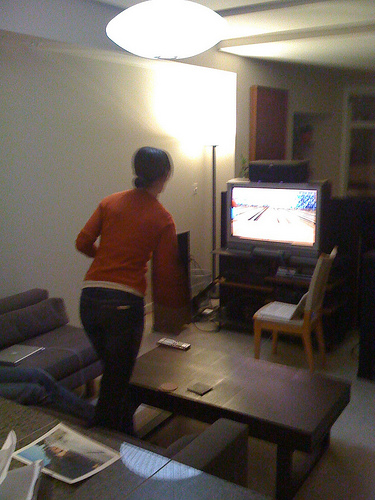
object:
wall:
[4, 36, 240, 282]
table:
[125, 340, 350, 500]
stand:
[319, 430, 330, 453]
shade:
[194, 111, 235, 155]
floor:
[148, 312, 371, 494]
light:
[105, 0, 228, 61]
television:
[226, 178, 321, 268]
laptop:
[260, 291, 309, 321]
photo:
[10, 421, 122, 487]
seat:
[253, 247, 339, 373]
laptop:
[0, 344, 45, 367]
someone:
[294, 124, 314, 161]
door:
[292, 111, 329, 181]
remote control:
[158, 337, 191, 351]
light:
[142, 59, 237, 161]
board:
[0, 59, 238, 276]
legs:
[276, 443, 293, 498]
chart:
[248, 84, 288, 162]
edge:
[297, 375, 352, 465]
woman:
[75, 146, 177, 435]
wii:
[277, 266, 295, 278]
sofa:
[0, 288, 89, 393]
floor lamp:
[211, 144, 219, 280]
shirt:
[76, 189, 177, 298]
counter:
[0, 395, 280, 497]